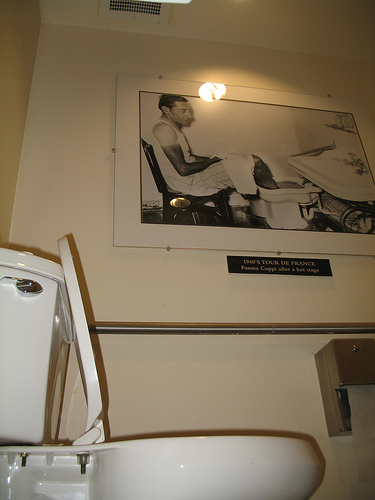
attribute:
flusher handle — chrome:
[2, 272, 42, 292]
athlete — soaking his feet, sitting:
[147, 92, 281, 210]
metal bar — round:
[89, 315, 374, 335]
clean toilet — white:
[0, 234, 325, 498]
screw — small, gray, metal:
[165, 245, 173, 252]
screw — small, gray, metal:
[276, 249, 280, 255]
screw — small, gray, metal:
[109, 146, 118, 151]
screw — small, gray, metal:
[157, 74, 162, 80]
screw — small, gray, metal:
[325, 93, 333, 98]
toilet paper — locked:
[317, 335, 374, 437]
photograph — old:
[104, 65, 374, 258]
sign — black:
[227, 254, 331, 277]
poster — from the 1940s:
[107, 68, 373, 256]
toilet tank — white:
[3, 240, 78, 445]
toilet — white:
[2, 276, 374, 496]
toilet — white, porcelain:
[0, 227, 325, 498]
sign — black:
[222, 254, 328, 274]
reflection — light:
[195, 80, 229, 105]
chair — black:
[119, 135, 265, 204]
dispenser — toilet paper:
[315, 319, 373, 445]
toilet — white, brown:
[13, 241, 331, 493]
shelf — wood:
[311, 338, 374, 437]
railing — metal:
[92, 322, 372, 335]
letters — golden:
[282, 255, 321, 266]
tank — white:
[0, 247, 70, 451]